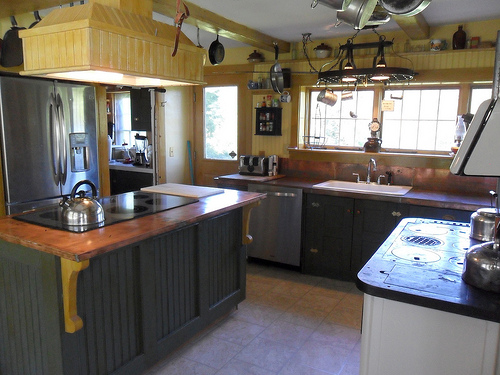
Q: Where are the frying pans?
A: Hanging from ceiling.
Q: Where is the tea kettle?
A: Range top.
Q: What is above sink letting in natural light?
A: Windows.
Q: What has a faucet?
A: Kitchen sink.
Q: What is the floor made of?
A: Tile.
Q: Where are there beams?
A: Ceiling.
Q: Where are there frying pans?
A: Ceiling beam.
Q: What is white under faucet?
A: Sink.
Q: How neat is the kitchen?
A: Spotless.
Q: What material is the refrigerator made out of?
A: Stainless steel.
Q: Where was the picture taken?
A: Kitchen.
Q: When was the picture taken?
A: During the daytime.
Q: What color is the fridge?
A: Gray.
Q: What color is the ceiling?
A: White.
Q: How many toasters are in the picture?
A: 1.